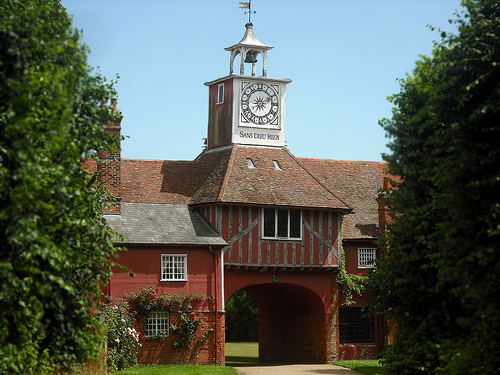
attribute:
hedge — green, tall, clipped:
[354, 1, 497, 373]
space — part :
[230, 307, 325, 374]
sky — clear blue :
[59, 0, 473, 162]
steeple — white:
[174, 16, 324, 160]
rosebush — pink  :
[101, 308, 142, 367]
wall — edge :
[203, 289, 227, 365]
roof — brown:
[87, 147, 407, 210]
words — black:
[238, 129, 280, 142]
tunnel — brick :
[224, 270, 317, 355]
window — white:
[155, 250, 195, 290]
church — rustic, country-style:
[88, 0, 413, 372]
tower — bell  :
[184, 21, 338, 254]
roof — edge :
[134, 214, 194, 239]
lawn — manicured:
[131, 344, 433, 373]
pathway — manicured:
[226, 337, 338, 370]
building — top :
[80, 156, 387, 362]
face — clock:
[244, 91, 277, 124]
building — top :
[77, 5, 402, 373]